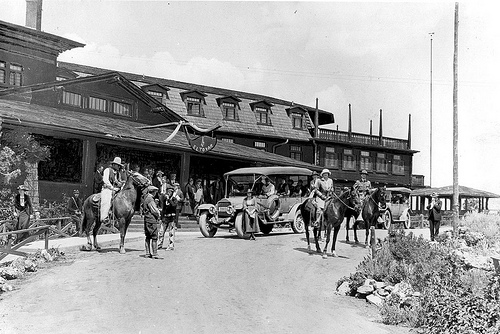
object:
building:
[0, 0, 499, 242]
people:
[10, 185, 33, 245]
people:
[252, 175, 306, 199]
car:
[197, 166, 315, 238]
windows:
[323, 146, 405, 176]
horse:
[295, 185, 362, 259]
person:
[158, 188, 178, 251]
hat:
[110, 157, 125, 167]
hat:
[320, 168, 332, 177]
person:
[240, 188, 260, 241]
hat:
[245, 188, 254, 193]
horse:
[79, 170, 152, 254]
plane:
[184, 126, 218, 154]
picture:
[0, 0, 500, 334]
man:
[426, 192, 443, 241]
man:
[99, 157, 125, 229]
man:
[142, 185, 164, 259]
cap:
[147, 186, 159, 193]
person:
[354, 169, 372, 222]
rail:
[0, 225, 49, 261]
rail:
[0, 215, 76, 245]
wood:
[4, 247, 11, 252]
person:
[311, 169, 335, 227]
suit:
[427, 200, 443, 240]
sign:
[135, 120, 223, 154]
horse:
[344, 185, 388, 249]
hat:
[358, 169, 369, 176]